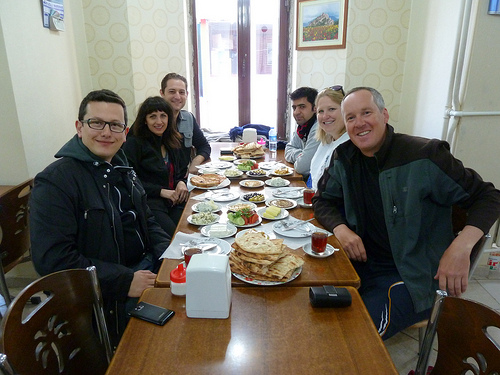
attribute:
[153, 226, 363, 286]
table — brown wooden 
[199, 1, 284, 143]
door — double , french, wood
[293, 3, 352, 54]
picture — framed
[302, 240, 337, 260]
small plate — white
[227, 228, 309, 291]
plate — paper 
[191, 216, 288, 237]
plate — round, white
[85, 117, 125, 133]
rim — black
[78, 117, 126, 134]
glasses — black, framed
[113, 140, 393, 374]
dining table — wooden dining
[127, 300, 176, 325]
phone — black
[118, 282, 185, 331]
cell phone — black cell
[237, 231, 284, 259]
bread — white, black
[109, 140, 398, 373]
table — wooden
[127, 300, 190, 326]
phone — black mobile 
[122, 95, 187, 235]
person — sitting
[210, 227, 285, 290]
round plate — white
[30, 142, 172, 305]
jacket — black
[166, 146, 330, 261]
plates — white